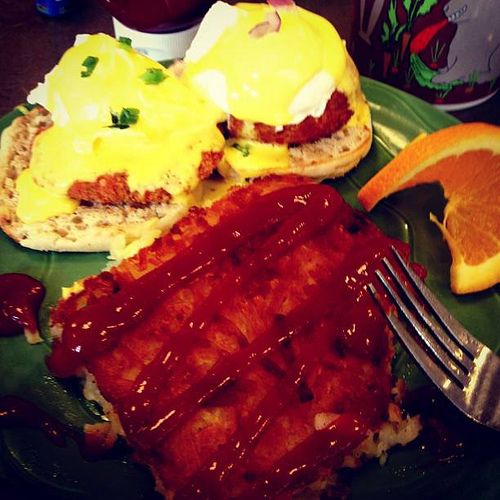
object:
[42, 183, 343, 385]
ribs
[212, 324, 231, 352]
bbq sauce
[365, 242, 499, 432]
fork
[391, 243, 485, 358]
prongs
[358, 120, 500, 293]
orange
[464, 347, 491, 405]
light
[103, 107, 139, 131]
onion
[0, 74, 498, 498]
plate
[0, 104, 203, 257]
biscuit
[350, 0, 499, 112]
mug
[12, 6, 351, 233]
sauce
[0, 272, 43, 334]
ketchup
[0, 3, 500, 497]
food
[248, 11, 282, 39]
mushroom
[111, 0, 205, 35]
lid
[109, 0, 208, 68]
bottle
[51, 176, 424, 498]
hash browns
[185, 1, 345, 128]
egg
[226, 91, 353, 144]
patty